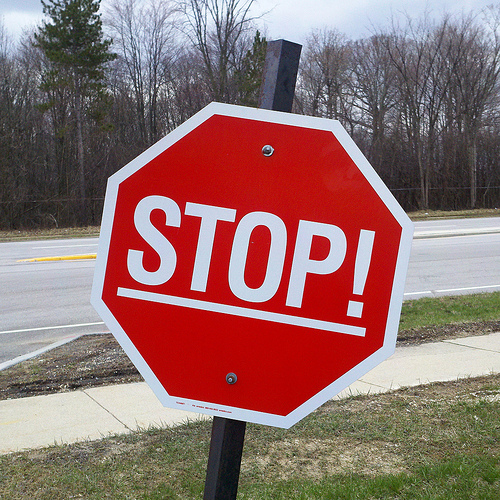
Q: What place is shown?
A: It is a road.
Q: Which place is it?
A: It is a road.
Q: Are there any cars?
A: No, there are no cars.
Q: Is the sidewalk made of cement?
A: Yes, the sidewalk is made of cement.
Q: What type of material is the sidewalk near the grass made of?
A: The sidewalk is made of cement.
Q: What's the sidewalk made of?
A: The sidewalk is made of concrete.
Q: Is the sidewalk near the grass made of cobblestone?
A: No, the sidewalk is made of cement.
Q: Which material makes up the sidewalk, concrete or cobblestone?
A: The sidewalk is made of concrete.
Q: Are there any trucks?
A: No, there are no trucks.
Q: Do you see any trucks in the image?
A: No, there are no trucks.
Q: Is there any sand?
A: Yes, there is sand.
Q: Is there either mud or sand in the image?
A: Yes, there is sand.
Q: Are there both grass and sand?
A: Yes, there are both sand and grass.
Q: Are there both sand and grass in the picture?
A: Yes, there are both sand and grass.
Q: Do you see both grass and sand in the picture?
A: Yes, there are both sand and grass.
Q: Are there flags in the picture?
A: No, there are no flags.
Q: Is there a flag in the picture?
A: No, there are no flags.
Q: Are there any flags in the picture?
A: No, there are no flags.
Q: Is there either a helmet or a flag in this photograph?
A: No, there are no flags or helmets.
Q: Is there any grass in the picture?
A: Yes, there is grass.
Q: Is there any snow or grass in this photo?
A: Yes, there is grass.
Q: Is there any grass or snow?
A: Yes, there is grass.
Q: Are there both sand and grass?
A: Yes, there are both grass and sand.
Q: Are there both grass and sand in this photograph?
A: Yes, there are both grass and sand.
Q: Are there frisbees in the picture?
A: No, there are no frisbees.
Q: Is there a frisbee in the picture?
A: No, there are no frisbees.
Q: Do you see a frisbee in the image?
A: No, there are no frisbees.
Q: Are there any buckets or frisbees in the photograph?
A: No, there are no frisbees or buckets.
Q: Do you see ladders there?
A: No, there are no ladders.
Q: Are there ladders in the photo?
A: No, there are no ladders.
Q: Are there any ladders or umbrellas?
A: No, there are no ladders or umbrellas.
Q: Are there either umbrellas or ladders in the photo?
A: No, there are no ladders or umbrellas.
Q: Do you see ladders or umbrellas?
A: No, there are no ladders or umbrellas.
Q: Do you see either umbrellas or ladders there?
A: No, there are no ladders or umbrellas.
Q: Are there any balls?
A: No, there are no balls.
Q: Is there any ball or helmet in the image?
A: No, there are no balls or helmets.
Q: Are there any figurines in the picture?
A: No, there are no figurines.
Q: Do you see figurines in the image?
A: No, there are no figurines.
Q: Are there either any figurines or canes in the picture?
A: No, there are no figurines or canes.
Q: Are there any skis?
A: No, there are no skis.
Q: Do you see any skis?
A: No, there are no skis.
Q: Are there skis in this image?
A: No, there are no skis.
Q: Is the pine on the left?
A: Yes, the pine is on the left of the image.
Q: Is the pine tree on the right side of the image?
A: No, the pine tree is on the left of the image.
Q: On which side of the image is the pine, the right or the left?
A: The pine is on the left of the image.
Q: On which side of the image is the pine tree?
A: The pine tree is on the left of the image.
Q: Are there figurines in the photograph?
A: No, there are no figurines.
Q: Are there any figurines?
A: No, there are no figurines.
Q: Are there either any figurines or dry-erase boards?
A: No, there are no figurines or dry-erase boards.